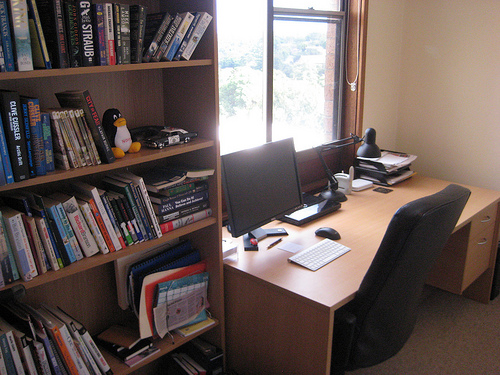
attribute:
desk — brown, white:
[228, 160, 494, 374]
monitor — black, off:
[220, 140, 313, 235]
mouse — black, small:
[311, 226, 343, 242]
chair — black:
[347, 191, 475, 361]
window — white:
[215, 6, 366, 143]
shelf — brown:
[0, 0, 240, 360]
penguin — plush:
[102, 106, 142, 158]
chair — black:
[334, 182, 475, 372]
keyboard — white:
[288, 237, 353, 272]